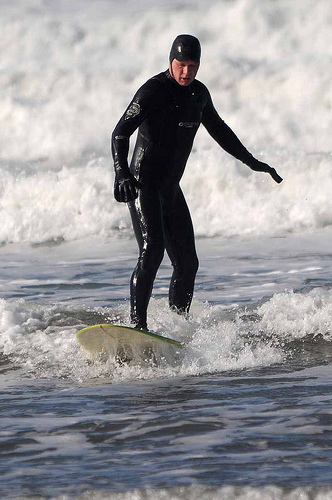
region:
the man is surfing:
[107, 29, 241, 367]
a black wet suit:
[94, 78, 277, 337]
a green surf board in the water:
[63, 319, 188, 362]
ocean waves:
[9, 123, 97, 282]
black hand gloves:
[111, 174, 143, 202]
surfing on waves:
[0, 289, 329, 382]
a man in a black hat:
[167, 34, 203, 88]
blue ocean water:
[149, 401, 313, 494]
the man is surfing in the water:
[73, 33, 245, 497]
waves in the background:
[14, 21, 330, 131]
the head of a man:
[164, 32, 201, 87]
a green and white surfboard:
[73, 317, 193, 364]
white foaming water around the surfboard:
[0, 280, 331, 383]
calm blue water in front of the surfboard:
[1, 381, 330, 499]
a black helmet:
[166, 32, 201, 81]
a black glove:
[112, 169, 143, 203]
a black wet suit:
[119, 66, 261, 321]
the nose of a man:
[182, 65, 189, 75]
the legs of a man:
[119, 182, 202, 325]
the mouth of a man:
[178, 75, 193, 82]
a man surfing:
[70, 36, 285, 430]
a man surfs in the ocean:
[29, 15, 317, 445]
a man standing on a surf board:
[77, 24, 270, 409]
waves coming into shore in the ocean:
[15, 12, 329, 251]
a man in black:
[86, 22, 281, 363]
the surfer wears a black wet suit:
[53, 10, 292, 416]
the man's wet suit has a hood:
[90, 14, 270, 428]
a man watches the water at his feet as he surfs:
[79, 23, 286, 452]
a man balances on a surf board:
[54, 20, 279, 422]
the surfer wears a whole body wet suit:
[84, 20, 286, 395]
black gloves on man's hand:
[109, 174, 164, 191]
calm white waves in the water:
[185, 427, 242, 445]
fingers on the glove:
[122, 186, 149, 204]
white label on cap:
[169, 45, 190, 52]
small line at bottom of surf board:
[94, 316, 126, 347]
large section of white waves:
[181, 315, 279, 368]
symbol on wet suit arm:
[112, 95, 160, 137]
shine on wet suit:
[109, 264, 155, 297]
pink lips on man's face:
[166, 71, 203, 84]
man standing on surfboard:
[85, 23, 279, 329]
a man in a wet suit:
[108, 35, 283, 319]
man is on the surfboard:
[65, 320, 190, 360]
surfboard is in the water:
[74, 320, 185, 361]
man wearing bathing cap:
[168, 33, 203, 93]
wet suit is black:
[107, 71, 282, 327]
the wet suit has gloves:
[110, 159, 282, 200]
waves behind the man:
[0, 0, 331, 246]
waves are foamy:
[2, 2, 331, 238]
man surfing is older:
[111, 33, 285, 328]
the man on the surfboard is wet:
[106, 33, 289, 320]